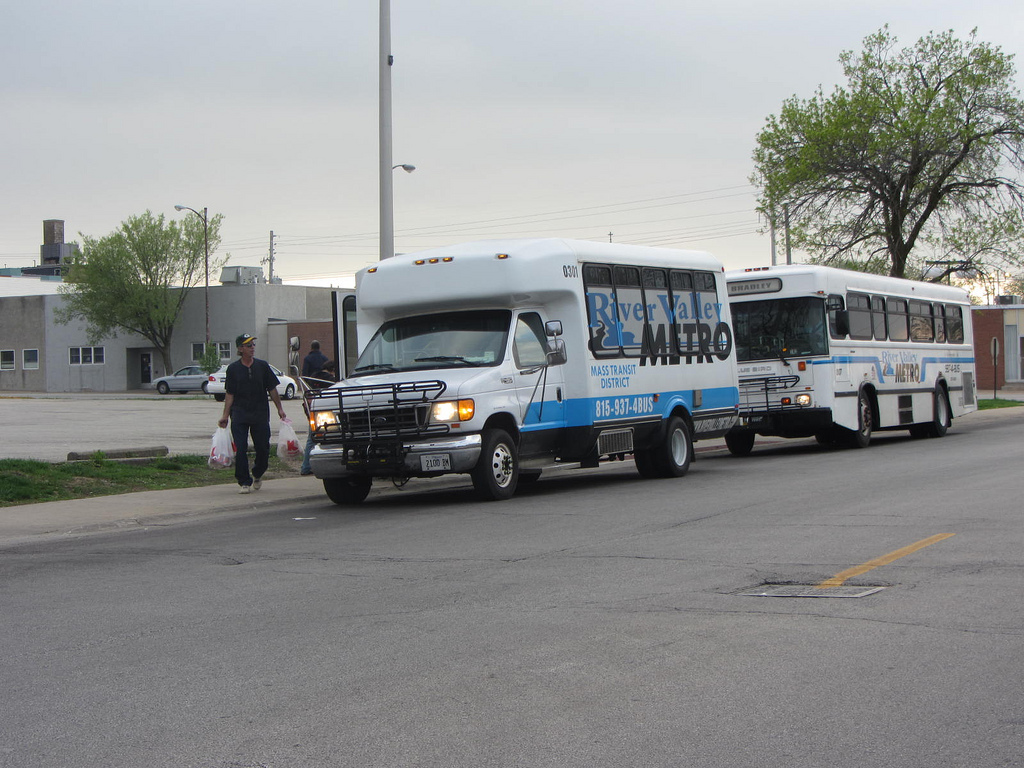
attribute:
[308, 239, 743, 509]
van — white, parked, blue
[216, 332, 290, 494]
man — carrying, walking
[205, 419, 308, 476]
bags — plastic, white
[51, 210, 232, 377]
tree — green, small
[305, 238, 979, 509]
buses — parked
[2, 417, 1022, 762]
road — non busy, grey, gray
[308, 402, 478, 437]
lights — on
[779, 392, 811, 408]
lights — on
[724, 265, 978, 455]
bus — behind, metro, white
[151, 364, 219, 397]
car — gray, silver, parked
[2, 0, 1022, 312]
sky — overcast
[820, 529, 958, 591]
line — yellow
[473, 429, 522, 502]
tire — black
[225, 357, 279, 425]
shirt — black